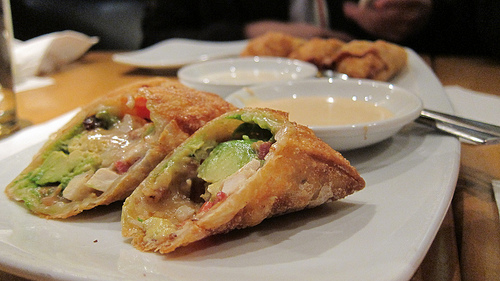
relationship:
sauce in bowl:
[313, 98, 354, 124] [260, 72, 401, 142]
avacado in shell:
[209, 134, 251, 168] [196, 119, 370, 225]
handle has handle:
[416, 109, 500, 147] [425, 108, 485, 142]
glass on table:
[1, 36, 16, 132] [64, 60, 112, 98]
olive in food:
[237, 123, 258, 138] [103, 59, 354, 253]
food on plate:
[103, 59, 354, 253] [344, 206, 431, 276]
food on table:
[103, 59, 354, 253] [64, 60, 112, 98]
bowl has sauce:
[260, 72, 401, 142] [313, 98, 354, 124]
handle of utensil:
[425, 108, 485, 142] [415, 105, 496, 139]